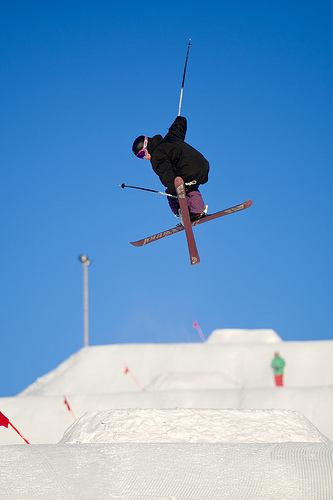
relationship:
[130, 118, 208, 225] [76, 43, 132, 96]
person in air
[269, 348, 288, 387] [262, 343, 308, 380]
person in clothing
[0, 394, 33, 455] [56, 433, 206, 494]
flag in snow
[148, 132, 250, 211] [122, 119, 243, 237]
coat on person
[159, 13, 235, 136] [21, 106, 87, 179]
pole in air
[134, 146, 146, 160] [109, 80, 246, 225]
goggles on person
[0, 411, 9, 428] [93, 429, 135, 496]
flag in snow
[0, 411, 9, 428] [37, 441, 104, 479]
flag in snow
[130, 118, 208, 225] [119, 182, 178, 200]
person doing stick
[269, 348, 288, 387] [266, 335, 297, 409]
person in snow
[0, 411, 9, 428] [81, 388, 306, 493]
flag next to ramps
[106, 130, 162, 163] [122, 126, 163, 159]
goggles on face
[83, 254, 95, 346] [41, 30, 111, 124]
pole in air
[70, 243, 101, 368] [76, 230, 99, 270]
pole with lights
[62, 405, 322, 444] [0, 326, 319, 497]
snow on ground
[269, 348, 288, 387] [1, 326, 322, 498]
person standing in snow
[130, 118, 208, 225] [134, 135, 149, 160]
person wearing goggles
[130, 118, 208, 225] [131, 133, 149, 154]
person wearing a helmet